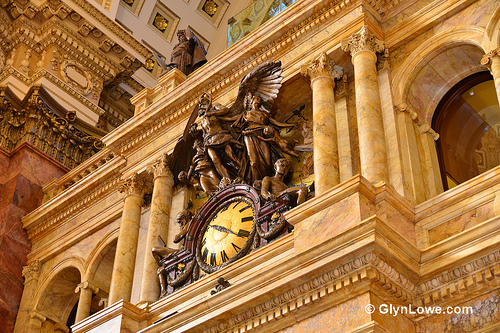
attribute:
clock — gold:
[196, 194, 258, 272]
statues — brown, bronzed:
[151, 60, 314, 266]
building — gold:
[0, 0, 500, 333]